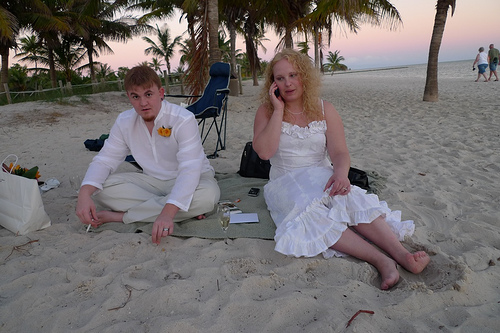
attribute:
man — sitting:
[73, 64, 225, 243]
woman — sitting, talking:
[249, 48, 432, 291]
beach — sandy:
[3, 58, 499, 332]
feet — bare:
[374, 246, 431, 291]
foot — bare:
[92, 207, 126, 224]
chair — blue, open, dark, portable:
[179, 60, 234, 158]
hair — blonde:
[265, 50, 324, 121]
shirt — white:
[78, 101, 215, 212]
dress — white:
[258, 92, 425, 259]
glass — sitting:
[216, 206, 235, 247]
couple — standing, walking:
[471, 42, 499, 83]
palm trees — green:
[1, 0, 459, 106]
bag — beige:
[1, 152, 55, 235]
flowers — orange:
[157, 124, 175, 136]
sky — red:
[2, 1, 498, 77]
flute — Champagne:
[207, 201, 241, 248]